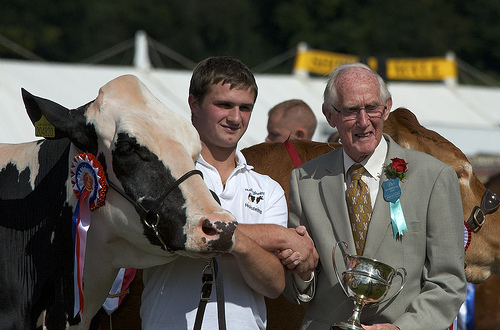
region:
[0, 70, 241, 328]
A black and white prize cow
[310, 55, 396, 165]
Man has white hair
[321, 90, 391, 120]
A pair of glasses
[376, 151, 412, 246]
Red rose and blue ribbon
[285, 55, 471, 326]
Man is holding a trophy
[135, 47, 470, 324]
Two men are shaking hands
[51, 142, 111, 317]
A ribbon on a cow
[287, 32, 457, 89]
A long and yellow sign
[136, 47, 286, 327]
Man wearing a white shirt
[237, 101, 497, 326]
A brown cow behind the men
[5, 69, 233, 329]
the cow is black and white in color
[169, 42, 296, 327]
the young man stands next to the cow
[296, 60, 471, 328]
an older gentleman holds a trophy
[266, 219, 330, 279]
the two men shake hands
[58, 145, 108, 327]
the cow wears a ribbon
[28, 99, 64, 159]
the cow has a yellow tag in its ear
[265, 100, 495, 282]
a brown cow is behind the older gentleman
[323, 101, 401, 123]
the older man is wearing glasses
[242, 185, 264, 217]
the young man has a cow on his shirt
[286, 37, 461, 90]
a yellow banner is in the background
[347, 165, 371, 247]
he is wearing a brown tie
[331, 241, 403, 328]
the winner throphy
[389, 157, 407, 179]
a red rose on the suit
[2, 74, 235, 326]
a cow on the scene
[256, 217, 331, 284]
they are shaking the hands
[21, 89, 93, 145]
one ear of the cow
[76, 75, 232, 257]
the head of the cow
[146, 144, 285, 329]
he wears a white polo shirt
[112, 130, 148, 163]
one eye of the cow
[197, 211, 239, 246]
the nose of the cow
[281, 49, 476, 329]
man wearing a suit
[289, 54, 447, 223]
man has gray hair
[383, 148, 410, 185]
a red rose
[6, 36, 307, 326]
boy next a cow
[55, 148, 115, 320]
a ribbon on side of cow's head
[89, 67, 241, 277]
head of cow is white and black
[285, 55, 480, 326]
man holds a trophy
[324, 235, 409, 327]
the trophy is silver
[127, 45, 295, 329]
boy wears a white shirt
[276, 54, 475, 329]
man wears a gray suit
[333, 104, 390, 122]
a man's eyeglasses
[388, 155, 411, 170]
a red rose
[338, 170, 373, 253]
part of a brown tie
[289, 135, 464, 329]
a gray suit coat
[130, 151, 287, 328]
a man's white shirt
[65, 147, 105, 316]
a red, white and blue ribbon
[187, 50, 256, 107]
a man's short cut brown hair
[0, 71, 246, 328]
part of a black and white cow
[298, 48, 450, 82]
a long yellow banner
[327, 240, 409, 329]
a small trophy